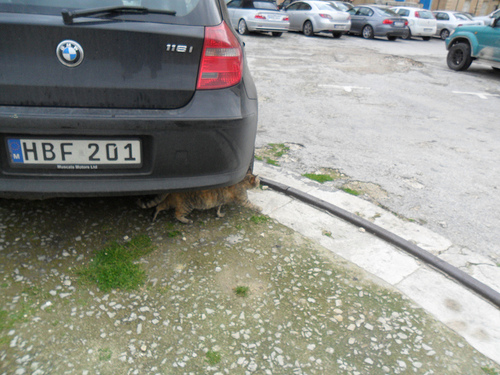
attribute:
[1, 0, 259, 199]
car — black, bmw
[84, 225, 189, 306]
grass — patchy, green, gree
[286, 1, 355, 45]
car — silver, parked, gra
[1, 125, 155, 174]
license plate — white, blue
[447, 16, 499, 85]
car — turquoise, blue, parked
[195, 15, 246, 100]
brake light — red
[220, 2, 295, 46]
vehicle — black, small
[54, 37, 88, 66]
logo — bmw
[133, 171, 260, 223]
cat — walking, orange, gray, walkig, gold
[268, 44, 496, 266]
street — quiet, rocky, bad